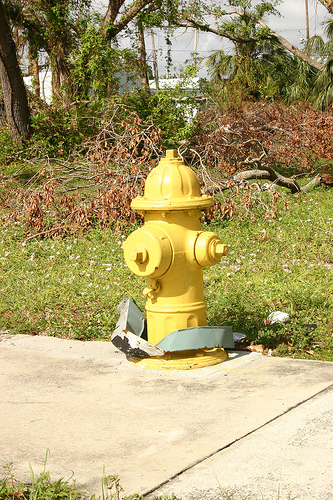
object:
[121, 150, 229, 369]
fire hydrant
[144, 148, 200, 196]
top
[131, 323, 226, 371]
base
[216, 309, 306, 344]
shadow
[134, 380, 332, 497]
cracks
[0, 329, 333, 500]
pavement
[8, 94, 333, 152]
bushes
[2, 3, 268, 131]
trees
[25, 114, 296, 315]
debris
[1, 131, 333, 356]
grass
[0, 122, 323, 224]
branch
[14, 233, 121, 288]
flowers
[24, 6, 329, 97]
leaves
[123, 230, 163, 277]
nozzle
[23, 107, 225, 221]
leaves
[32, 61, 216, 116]
building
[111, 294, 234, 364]
scrap metal